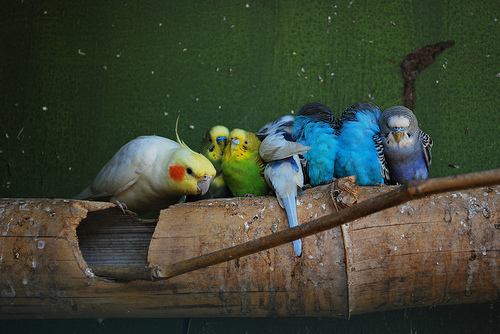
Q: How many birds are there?
A: 7.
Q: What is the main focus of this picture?
A: The birds.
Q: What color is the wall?
A: Green.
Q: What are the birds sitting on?
A: A branch.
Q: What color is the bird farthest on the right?
A: Blue.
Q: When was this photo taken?
A: During the day.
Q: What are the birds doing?
A: Cuddling.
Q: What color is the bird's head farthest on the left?
A: Yellow.